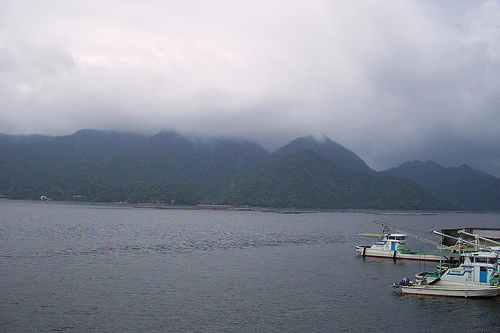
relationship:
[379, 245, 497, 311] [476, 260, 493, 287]
boat has door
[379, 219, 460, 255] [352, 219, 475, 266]
crane on boat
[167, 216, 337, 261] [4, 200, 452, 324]
ripples along surface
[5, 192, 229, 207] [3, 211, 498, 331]
homes along edge of water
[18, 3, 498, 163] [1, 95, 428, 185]
fog on hilltops